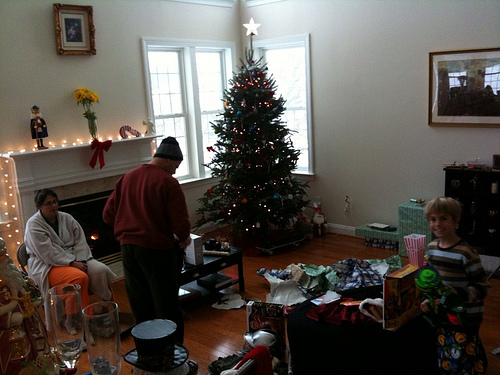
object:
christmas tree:
[189, 17, 311, 242]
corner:
[232, 0, 246, 62]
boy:
[414, 196, 488, 374]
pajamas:
[422, 284, 487, 375]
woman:
[23, 188, 118, 334]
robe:
[23, 210, 117, 332]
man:
[103, 136, 191, 345]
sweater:
[103, 163, 192, 249]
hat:
[156, 136, 183, 157]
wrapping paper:
[256, 258, 384, 306]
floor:
[183, 232, 408, 375]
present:
[354, 221, 399, 250]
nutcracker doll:
[29, 105, 49, 147]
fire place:
[7, 132, 163, 284]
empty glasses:
[50, 283, 123, 374]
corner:
[0, 237, 77, 374]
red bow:
[89, 138, 112, 170]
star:
[241, 18, 261, 37]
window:
[147, 45, 226, 182]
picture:
[431, 50, 500, 124]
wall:
[240, 0, 499, 228]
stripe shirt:
[427, 238, 493, 314]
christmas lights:
[0, 131, 157, 245]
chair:
[16, 242, 28, 275]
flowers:
[72, 86, 100, 103]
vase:
[88, 119, 98, 139]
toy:
[415, 267, 444, 292]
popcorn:
[408, 234, 424, 238]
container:
[404, 233, 426, 267]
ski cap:
[156, 136, 184, 157]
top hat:
[123, 318, 189, 372]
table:
[185, 360, 198, 375]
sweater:
[42, 215, 58, 236]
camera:
[240, 219, 260, 231]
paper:
[398, 215, 416, 235]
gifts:
[355, 198, 432, 256]